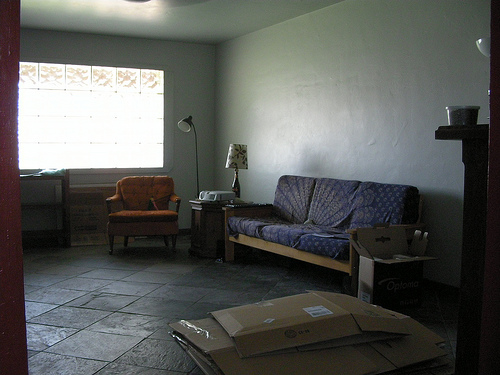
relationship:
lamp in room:
[176, 116, 200, 198] [8, 8, 478, 355]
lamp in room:
[221, 140, 250, 199] [8, 8, 478, 355]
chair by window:
[100, 170, 184, 255] [19, 56, 178, 174]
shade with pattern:
[297, 152, 328, 175] [227, 145, 247, 170]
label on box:
[302, 305, 333, 318] [213, 289, 417, 356]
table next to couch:
[182, 196, 241, 256] [222, 172, 439, 312]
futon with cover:
[226, 167, 417, 307] [257, 182, 363, 243]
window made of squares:
[18, 62, 168, 175] [18, 66, 165, 167]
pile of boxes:
[171, 288, 451, 373] [170, 282, 469, 372]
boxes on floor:
[170, 282, 469, 372] [24, 237, 465, 373]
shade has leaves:
[224, 143, 252, 180] [227, 150, 246, 164]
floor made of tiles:
[18, 247, 469, 371] [20, 246, 469, 372]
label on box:
[304, 299, 337, 323] [205, 289, 415, 350]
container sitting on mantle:
[438, 102, 486, 130] [433, 122, 499, 142]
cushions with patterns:
[231, 166, 416, 261] [281, 179, 344, 219]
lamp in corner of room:
[173, 110, 203, 199] [4, 2, 498, 372]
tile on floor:
[121, 293, 190, 321] [24, 237, 465, 373]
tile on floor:
[87, 302, 180, 341] [24, 237, 465, 373]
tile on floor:
[118, 335, 193, 370] [18, 247, 469, 371]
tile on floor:
[105, 275, 165, 305] [24, 237, 465, 373]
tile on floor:
[81, 266, 124, 289] [24, 237, 465, 373]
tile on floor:
[32, 281, 82, 303] [18, 247, 469, 371]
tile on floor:
[40, 260, 90, 280] [18, 247, 469, 371]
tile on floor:
[49, 325, 149, 362] [24, 237, 465, 373]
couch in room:
[222, 172, 439, 312] [4, 2, 498, 372]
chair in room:
[106, 175, 182, 255] [4, 2, 498, 372]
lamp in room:
[176, 116, 200, 198] [4, 2, 498, 372]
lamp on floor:
[176, 116, 200, 198] [24, 237, 465, 373]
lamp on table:
[224, 143, 248, 203] [187, 202, 225, 252]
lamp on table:
[224, 143, 248, 203] [191, 199, 241, 254]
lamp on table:
[224, 143, 248, 203] [189, 195, 231, 256]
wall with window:
[11, 40, 226, 249] [18, 62, 168, 175]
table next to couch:
[188, 198, 274, 258] [221, 176, 421, 297]